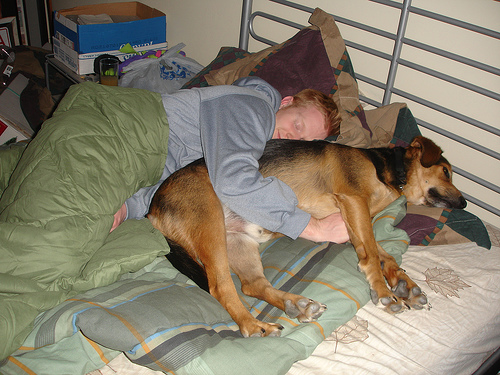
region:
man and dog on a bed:
[6, 45, 477, 342]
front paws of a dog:
[369, 269, 439, 327]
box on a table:
[51, 6, 176, 78]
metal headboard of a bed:
[370, 3, 494, 113]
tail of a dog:
[154, 226, 211, 293]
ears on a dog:
[394, 96, 449, 165]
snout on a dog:
[425, 178, 474, 212]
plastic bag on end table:
[117, 37, 208, 88]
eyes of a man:
[293, 108, 316, 145]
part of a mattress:
[314, 318, 319, 330]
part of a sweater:
[236, 173, 244, 184]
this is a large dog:
[140, 103, 495, 328]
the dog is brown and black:
[148, 121, 478, 341]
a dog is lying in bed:
[147, 136, 491, 343]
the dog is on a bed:
[145, 134, 492, 356]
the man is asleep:
[86, 50, 496, 345]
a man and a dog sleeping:
[117, 50, 472, 342]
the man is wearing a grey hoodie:
[102, 45, 379, 278]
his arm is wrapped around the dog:
[84, 45, 445, 290]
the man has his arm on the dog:
[102, 15, 399, 310]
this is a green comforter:
[20, 67, 360, 374]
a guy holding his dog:
[174, 104, 359, 297]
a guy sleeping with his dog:
[194, 86, 336, 218]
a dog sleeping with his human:
[175, 152, 494, 271]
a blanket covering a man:
[51, 113, 186, 198]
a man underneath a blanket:
[117, 84, 291, 141]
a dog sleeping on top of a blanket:
[153, 180, 490, 248]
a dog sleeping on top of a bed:
[143, 160, 485, 285]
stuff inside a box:
[52, 1, 169, 45]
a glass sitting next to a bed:
[91, 56, 121, 86]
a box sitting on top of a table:
[48, 17, 96, 78]